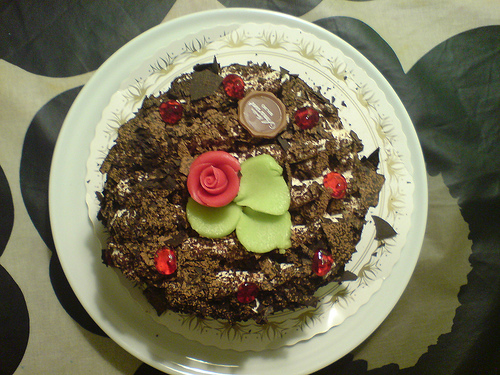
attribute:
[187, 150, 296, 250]
leaves — green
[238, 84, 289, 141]
circle — brown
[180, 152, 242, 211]
rose — red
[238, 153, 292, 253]
icing — green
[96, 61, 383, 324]
cake — chocolate, decorated, brown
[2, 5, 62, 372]
table cloth — black, white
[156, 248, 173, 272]
jelly — red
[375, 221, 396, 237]
piece — chocolate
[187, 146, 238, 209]
rose — pink, fondant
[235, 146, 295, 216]
leaf — green, fondant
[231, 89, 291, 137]
brown disc — brown 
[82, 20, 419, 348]
doily — white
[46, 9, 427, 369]
plate — white, round, ceramic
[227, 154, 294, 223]
candy petal — yellow 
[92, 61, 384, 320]
dessert — yummy 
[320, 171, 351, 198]
red flower — red 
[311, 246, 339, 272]
red flower — red 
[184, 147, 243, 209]
rose — red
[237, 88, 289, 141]
pendant — brown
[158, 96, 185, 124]
candy — red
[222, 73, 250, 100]
candy — red